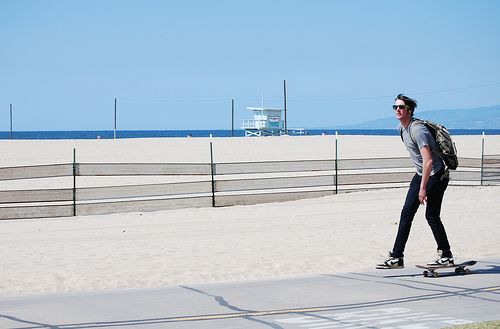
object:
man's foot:
[374, 255, 405, 270]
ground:
[2, 134, 496, 325]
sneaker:
[427, 250, 456, 268]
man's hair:
[395, 92, 418, 116]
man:
[374, 94, 455, 273]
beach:
[3, 135, 499, 298]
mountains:
[346, 105, 498, 129]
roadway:
[1, 260, 496, 326]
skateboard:
[415, 260, 480, 277]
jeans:
[389, 167, 450, 257]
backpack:
[399, 118, 460, 170]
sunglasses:
[392, 105, 412, 111]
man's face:
[393, 99, 405, 119]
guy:
[377, 93, 457, 269]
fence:
[0, 133, 500, 220]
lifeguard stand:
[240, 93, 304, 136]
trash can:
[209, 133, 213, 142]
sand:
[0, 135, 495, 300]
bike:
[274, 300, 471, 328]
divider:
[83, 283, 497, 324]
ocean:
[0, 129, 499, 139]